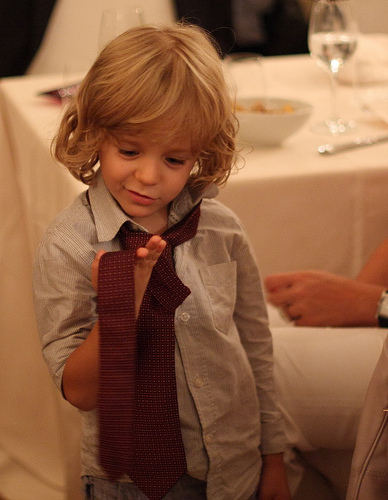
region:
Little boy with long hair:
[53, 27, 285, 235]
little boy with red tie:
[35, 180, 268, 483]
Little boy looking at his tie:
[47, 83, 296, 491]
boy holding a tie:
[31, 212, 206, 377]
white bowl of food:
[231, 78, 340, 161]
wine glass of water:
[295, 4, 375, 106]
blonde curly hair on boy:
[28, 75, 120, 197]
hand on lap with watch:
[254, 249, 387, 361]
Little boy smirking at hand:
[87, 146, 206, 250]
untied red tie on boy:
[99, 216, 258, 334]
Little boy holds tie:
[37, 28, 308, 453]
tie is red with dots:
[55, 205, 237, 492]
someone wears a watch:
[259, 253, 387, 332]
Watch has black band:
[364, 270, 386, 348]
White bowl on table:
[226, 90, 319, 155]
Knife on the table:
[319, 115, 386, 177]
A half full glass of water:
[302, 9, 359, 148]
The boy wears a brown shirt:
[29, 178, 298, 499]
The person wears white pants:
[256, 280, 386, 462]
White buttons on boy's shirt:
[170, 310, 219, 407]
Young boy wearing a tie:
[25, 36, 298, 495]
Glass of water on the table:
[304, 3, 364, 138]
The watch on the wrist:
[371, 281, 387, 327]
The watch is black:
[374, 282, 387, 333]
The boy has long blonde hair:
[47, 20, 278, 257]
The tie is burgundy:
[97, 199, 202, 494]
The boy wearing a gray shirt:
[30, 175, 303, 482]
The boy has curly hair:
[37, 22, 244, 208]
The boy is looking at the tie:
[25, 24, 281, 480]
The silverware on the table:
[313, 134, 387, 158]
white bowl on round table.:
[231, 82, 315, 152]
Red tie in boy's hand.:
[80, 247, 148, 492]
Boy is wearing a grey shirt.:
[180, 261, 265, 498]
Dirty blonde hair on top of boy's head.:
[84, 35, 236, 120]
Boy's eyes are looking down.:
[86, 128, 212, 174]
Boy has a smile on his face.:
[79, 94, 222, 232]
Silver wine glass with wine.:
[297, 2, 369, 135]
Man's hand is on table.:
[264, 252, 385, 340]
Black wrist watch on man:
[368, 285, 386, 332]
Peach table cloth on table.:
[256, 149, 316, 201]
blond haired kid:
[79, 28, 242, 168]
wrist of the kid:
[251, 434, 299, 494]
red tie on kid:
[118, 382, 194, 476]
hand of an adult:
[263, 250, 366, 338]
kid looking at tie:
[106, 97, 209, 203]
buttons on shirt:
[169, 286, 207, 399]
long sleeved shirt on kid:
[78, 218, 288, 395]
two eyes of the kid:
[97, 121, 210, 179]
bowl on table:
[239, 73, 302, 138]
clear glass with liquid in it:
[304, 6, 367, 68]